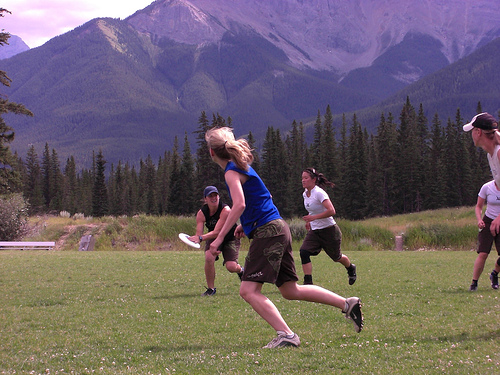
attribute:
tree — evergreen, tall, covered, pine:
[267, 90, 447, 210]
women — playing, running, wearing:
[111, 82, 487, 367]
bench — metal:
[0, 231, 81, 259]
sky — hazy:
[46, 8, 71, 30]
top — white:
[285, 184, 342, 237]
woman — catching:
[178, 160, 237, 291]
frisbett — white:
[178, 224, 200, 249]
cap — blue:
[193, 174, 221, 218]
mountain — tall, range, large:
[70, 6, 151, 87]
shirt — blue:
[226, 151, 295, 230]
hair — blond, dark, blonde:
[210, 128, 249, 160]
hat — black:
[195, 169, 229, 207]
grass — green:
[99, 295, 207, 341]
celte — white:
[6, 219, 108, 294]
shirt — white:
[294, 187, 330, 232]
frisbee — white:
[172, 219, 217, 258]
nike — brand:
[297, 192, 319, 218]